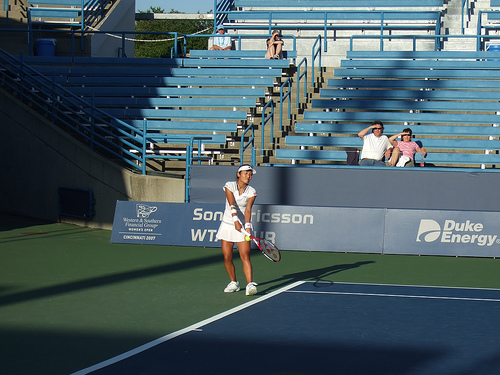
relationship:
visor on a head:
[239, 164, 259, 174] [232, 163, 257, 185]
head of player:
[232, 163, 257, 185] [214, 163, 269, 295]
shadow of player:
[254, 257, 374, 297] [215, 164, 257, 295]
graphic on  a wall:
[136, 202, 158, 219] [109, 199, 499, 256]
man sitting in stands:
[358, 120, 393, 169] [403, 56, 488, 114]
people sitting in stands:
[388, 128, 424, 171] [403, 56, 488, 114]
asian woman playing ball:
[179, 142, 288, 309] [245, 236, 251, 242]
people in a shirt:
[389, 128, 426, 168] [395, 135, 419, 160]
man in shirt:
[355, 117, 394, 169] [358, 131, 392, 159]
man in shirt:
[265, 28, 285, 62] [356, 124, 391, 175]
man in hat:
[210, 25, 232, 59] [215, 23, 226, 30]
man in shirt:
[210, 25, 232, 59] [209, 32, 231, 49]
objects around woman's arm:
[228, 205, 239, 224] [220, 180, 242, 231]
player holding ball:
[215, 164, 257, 295] [244, 236, 251, 241]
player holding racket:
[215, 164, 257, 295] [240, 227, 282, 262]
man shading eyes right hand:
[358, 120, 393, 169] [368, 122, 382, 130]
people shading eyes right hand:
[389, 128, 426, 168] [393, 130, 411, 140]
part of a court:
[225, 319, 490, 359] [170, 276, 488, 343]